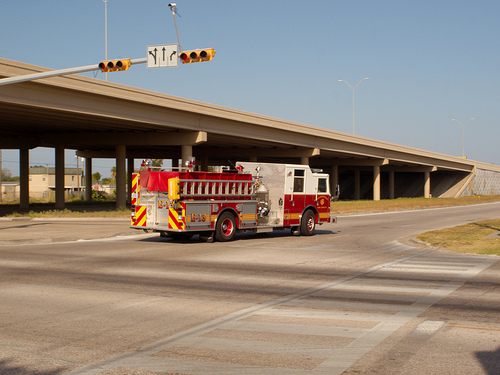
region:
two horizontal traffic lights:
[88, 39, 229, 87]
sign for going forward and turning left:
[145, 40, 161, 72]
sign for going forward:
[159, 42, 167, 70]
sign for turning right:
[166, 38, 177, 69]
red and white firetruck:
[125, 142, 340, 249]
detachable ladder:
[170, 175, 256, 204]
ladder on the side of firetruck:
[169, 175, 266, 201]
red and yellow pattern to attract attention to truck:
[124, 169, 152, 229]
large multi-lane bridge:
[2, 55, 494, 205]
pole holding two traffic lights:
[2, 41, 223, 88]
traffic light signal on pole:
[176, 50, 220, 64]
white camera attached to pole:
[160, 2, 190, 22]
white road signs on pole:
[149, 45, 176, 66]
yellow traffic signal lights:
[95, 55, 135, 71]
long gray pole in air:
[0, 58, 96, 87]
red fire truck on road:
[132, 166, 341, 240]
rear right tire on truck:
[217, 206, 238, 239]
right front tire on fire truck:
[300, 205, 321, 237]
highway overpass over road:
[256, 118, 421, 156]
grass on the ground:
[446, 222, 472, 253]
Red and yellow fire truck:
[130, 148, 332, 241]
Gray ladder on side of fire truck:
[179, 178, 254, 198]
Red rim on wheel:
[213, 210, 235, 240]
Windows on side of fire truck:
[291, 164, 331, 194]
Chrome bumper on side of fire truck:
[328, 212, 335, 222]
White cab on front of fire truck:
[235, 158, 332, 227]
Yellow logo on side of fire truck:
[185, 203, 258, 228]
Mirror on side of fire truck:
[331, 180, 341, 199]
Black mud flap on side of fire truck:
[197, 230, 214, 242]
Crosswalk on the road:
[67, 247, 497, 374]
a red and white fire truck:
[125, 155, 332, 245]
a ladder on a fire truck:
[165, 175, 257, 200]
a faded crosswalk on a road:
[100, 245, 492, 370]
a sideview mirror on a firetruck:
[327, 180, 339, 200]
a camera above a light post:
[161, 0, 181, 45]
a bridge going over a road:
[0, 52, 496, 192]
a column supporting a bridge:
[51, 142, 66, 214]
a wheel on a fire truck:
[214, 205, 238, 242]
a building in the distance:
[23, 163, 84, 206]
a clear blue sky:
[1, 3, 496, 175]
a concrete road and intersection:
[0, 200, 499, 374]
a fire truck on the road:
[128, 157, 338, 240]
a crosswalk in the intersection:
[62, 249, 499, 374]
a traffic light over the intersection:
[0, 46, 215, 86]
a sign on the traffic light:
[145, 43, 178, 69]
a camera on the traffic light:
[167, 2, 181, 51]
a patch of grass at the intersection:
[417, 217, 499, 255]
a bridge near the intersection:
[0, 56, 499, 213]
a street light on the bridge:
[337, 76, 370, 135]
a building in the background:
[0, 166, 127, 201]